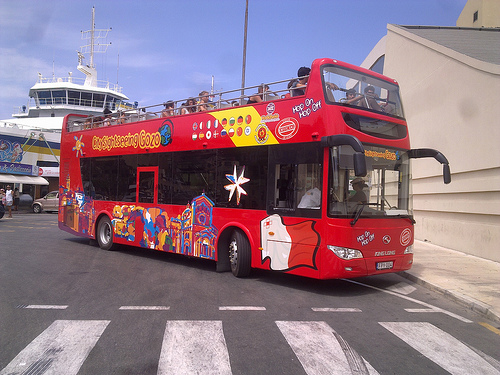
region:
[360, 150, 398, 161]
digital sign tells destination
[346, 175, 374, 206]
the driver of the bus inside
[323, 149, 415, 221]
front window of bus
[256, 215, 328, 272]
a flag painted on bus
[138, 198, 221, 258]
colorful mural on bus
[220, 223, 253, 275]
wheel on the bus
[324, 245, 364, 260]
headlights on bus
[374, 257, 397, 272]
license plate on bus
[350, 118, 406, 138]
place for sign empty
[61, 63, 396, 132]
People riding on roof of bus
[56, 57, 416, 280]
A red double decker bus.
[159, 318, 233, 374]
A white line on the road.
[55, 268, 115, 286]
Part of the road.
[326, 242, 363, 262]
The front light on the bus.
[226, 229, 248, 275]
The front wheel on the bus.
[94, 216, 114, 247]
The rear wheel on the bus.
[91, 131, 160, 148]
Yellow and red writing .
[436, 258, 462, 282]
Part of the sidewalk.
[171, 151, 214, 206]
A window on the bus.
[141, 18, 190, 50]
part of the blue sky.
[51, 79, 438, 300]
A big red passenger bus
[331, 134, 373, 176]
A black bus side mirror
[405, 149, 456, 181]
A black bus side mirror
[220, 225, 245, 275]
A black bus tyre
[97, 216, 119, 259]
A black bus tyre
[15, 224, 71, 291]
A grey tarmac road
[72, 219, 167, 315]
A grey tarmac road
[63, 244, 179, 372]
A grey tarmac marked road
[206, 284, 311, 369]
A grey tarmac marked road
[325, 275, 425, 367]
A grey tarmac marked road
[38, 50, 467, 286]
a red double decker bus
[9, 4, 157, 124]
the top of a structure can be seen behind the bus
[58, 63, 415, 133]
the top of the bus is full of people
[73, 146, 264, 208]
the buses windows are tinted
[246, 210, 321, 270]
the bus has a flag painted on its side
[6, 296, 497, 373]
the road has a crossing area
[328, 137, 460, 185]
the bus has two large review mirrors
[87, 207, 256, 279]
two of the buses tires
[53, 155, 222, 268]
the bus has a festive painting on it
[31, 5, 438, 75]
the sky is blue with a few white clouds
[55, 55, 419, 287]
A double decker bus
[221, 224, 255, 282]
A round black tire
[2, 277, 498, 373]
White lines on the pavement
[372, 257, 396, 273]
A rectangular license plate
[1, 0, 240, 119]
White clouds in the sky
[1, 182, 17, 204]
Person wearing a white shirt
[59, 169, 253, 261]
Drawings on the side of a bus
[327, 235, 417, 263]
Headlights on the bus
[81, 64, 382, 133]
People sitting on the top deck of a bus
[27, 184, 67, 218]
A car in the background